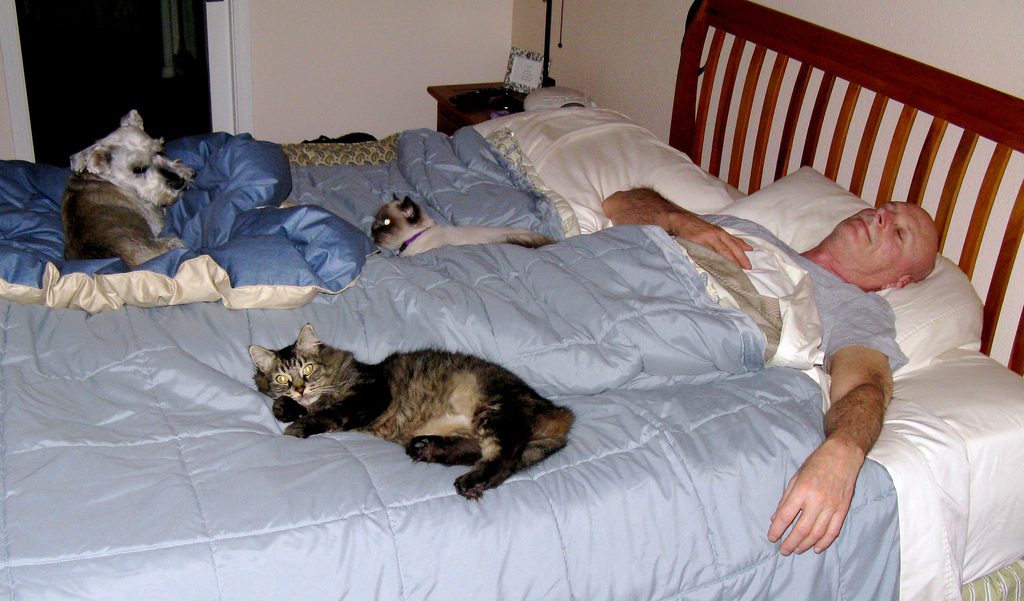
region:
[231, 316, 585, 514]
cat laying in the bed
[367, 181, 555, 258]
cat laying in the bed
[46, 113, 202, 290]
dog on the bed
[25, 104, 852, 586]
animals laying on the bed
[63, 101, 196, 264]
cat laying in the bed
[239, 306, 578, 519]
cat laying in the bed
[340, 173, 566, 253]
cat laying in the bed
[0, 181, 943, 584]
Guy is sleeping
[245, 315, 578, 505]
Cat with eyes wide open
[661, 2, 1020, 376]
a wooden headboard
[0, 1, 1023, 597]
Guy and cats on the bed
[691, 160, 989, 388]
Head on white pillow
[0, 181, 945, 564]
Guy sleeping is white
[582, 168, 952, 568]
man sleeping on back in bed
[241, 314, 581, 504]
black and grey cat on blue bed spread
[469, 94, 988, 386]
two white pillows on bed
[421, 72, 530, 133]
wooden night stand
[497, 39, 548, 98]
white and green card on night stand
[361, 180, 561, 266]
white and black cat on blue bed spread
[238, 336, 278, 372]
ear on grey and black cat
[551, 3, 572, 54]
black pull string above wooden night stand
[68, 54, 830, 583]
cats on the bed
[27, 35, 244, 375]
dog on the bed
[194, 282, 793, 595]
black and grey cat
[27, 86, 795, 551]
blue sheets on the bed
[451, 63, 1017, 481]
white pillows on the bed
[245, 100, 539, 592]
two cats on the bed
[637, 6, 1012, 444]
a wooden headboard in the background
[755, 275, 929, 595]
hair on the hand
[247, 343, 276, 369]
ear of a cat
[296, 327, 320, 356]
ear of a cat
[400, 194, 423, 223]
ear of a cat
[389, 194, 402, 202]
ear of a cat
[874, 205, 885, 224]
nose of a man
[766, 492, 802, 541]
finger of a man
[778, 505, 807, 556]
finger of a man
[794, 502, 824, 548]
finger of a man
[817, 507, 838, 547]
finger of a man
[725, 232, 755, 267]
finger of a man